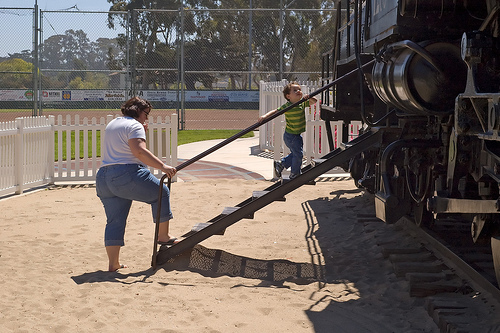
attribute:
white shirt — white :
[93, 111, 161, 171]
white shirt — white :
[103, 111, 150, 171]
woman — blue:
[90, 92, 182, 280]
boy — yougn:
[269, 80, 321, 186]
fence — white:
[0, 103, 180, 201]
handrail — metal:
[156, 55, 381, 195]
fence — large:
[68, 27, 154, 97]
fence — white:
[14, 121, 78, 183]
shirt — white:
[101, 109, 141, 165]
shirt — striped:
[281, 105, 304, 133]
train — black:
[323, 15, 463, 193]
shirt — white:
[97, 116, 147, 161]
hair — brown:
[117, 94, 156, 120]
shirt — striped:
[278, 103, 299, 133]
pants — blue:
[267, 124, 307, 180]